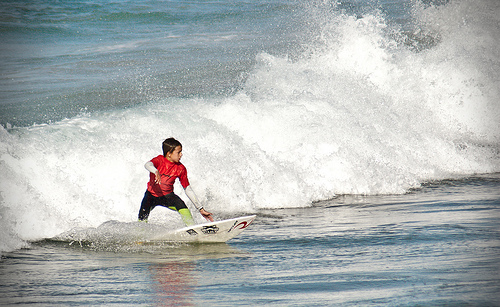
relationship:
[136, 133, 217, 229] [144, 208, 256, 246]
boy riding surfboard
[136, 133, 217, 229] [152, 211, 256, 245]
boy standing on surfboard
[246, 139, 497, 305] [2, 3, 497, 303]
water on ocean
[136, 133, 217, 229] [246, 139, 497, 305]
boy surfing in front of water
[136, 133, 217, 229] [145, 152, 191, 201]
boy wearing shirt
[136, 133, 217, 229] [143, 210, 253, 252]
boy balancing on surfboard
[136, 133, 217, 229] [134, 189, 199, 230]
boy wearing pants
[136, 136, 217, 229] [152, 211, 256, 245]
boy riding surfboard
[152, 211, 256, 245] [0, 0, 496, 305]
surfboard in water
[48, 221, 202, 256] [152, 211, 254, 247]
water splashing off surfboard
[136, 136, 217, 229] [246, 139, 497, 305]
boy surfing ahead of water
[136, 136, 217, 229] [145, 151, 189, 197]
boy wearing shirt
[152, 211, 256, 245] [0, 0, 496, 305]
surfboard ridden in water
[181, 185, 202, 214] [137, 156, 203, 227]
sleeve of wet suit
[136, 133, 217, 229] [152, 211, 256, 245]
boy on surfboard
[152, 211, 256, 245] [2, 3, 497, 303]
surfboard in ocean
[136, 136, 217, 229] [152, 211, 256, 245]
boy maneuvering surfboard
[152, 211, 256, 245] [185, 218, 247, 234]
surfboard with design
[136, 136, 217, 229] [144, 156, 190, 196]
boy wearing shirt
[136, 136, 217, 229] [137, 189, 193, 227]
boy wearing pants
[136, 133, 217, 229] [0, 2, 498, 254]
boy riding ocean wave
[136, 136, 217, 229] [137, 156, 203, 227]
boy wearing wet suit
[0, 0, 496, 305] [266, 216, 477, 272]
water has ripples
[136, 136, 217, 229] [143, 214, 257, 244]
boy on surfboard